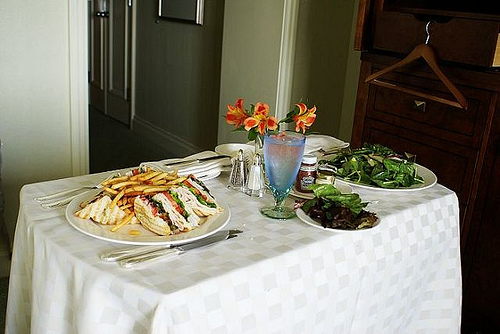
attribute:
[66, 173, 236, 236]
plate — white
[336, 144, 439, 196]
plate — white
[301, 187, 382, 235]
plate — small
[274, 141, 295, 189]
water — clear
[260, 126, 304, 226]
glass — large, blue, green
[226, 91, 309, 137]
flowers — orange, red, yellow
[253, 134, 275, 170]
vase — clear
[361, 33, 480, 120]
hanger — wooden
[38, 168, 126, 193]
utensils — silver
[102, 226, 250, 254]
utensils — silver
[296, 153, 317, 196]
bottle — small, red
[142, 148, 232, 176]
napkin — white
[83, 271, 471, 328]
tablecloth — white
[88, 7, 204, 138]
hallway — darkened